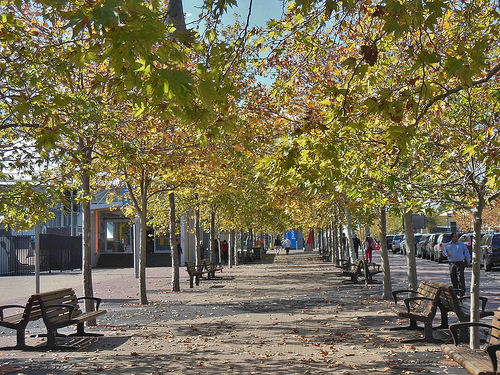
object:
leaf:
[144, 67, 187, 106]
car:
[416, 235, 430, 259]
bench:
[361, 259, 385, 284]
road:
[349, 244, 499, 316]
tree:
[349, 1, 405, 304]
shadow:
[424, 271, 499, 300]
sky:
[195, 2, 350, 96]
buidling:
[1, 164, 196, 269]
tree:
[121, 34, 167, 305]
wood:
[35, 287, 107, 324]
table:
[254, 245, 264, 260]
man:
[442, 233, 473, 292]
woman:
[361, 235, 379, 262]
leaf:
[360, 294, 371, 306]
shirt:
[221, 243, 230, 253]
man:
[351, 233, 361, 257]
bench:
[338, 259, 364, 286]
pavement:
[84, 252, 463, 374]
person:
[283, 237, 293, 256]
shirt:
[440, 240, 470, 263]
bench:
[185, 261, 208, 288]